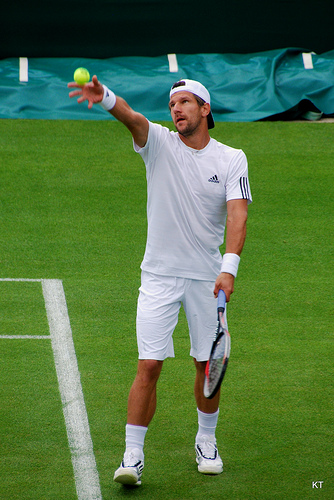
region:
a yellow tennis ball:
[44, 61, 107, 92]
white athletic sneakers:
[105, 416, 278, 499]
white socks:
[105, 393, 277, 481]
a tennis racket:
[174, 260, 277, 444]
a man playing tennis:
[53, 50, 253, 395]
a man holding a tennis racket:
[101, 84, 249, 384]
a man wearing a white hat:
[133, 62, 245, 155]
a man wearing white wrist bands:
[58, 61, 276, 316]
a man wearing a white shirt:
[76, 58, 257, 283]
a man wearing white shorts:
[89, 40, 252, 422]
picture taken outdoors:
[19, 315, 324, 494]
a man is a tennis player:
[94, 317, 284, 480]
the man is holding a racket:
[142, 339, 272, 413]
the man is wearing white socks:
[127, 412, 262, 475]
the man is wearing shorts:
[125, 341, 292, 391]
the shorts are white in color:
[127, 326, 235, 351]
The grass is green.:
[269, 325, 303, 445]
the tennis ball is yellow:
[62, 58, 147, 115]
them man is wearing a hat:
[165, 79, 318, 152]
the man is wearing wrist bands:
[217, 256, 314, 293]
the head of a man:
[161, 69, 215, 144]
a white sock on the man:
[194, 402, 220, 442]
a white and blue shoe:
[189, 433, 226, 475]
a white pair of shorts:
[131, 264, 232, 365]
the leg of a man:
[114, 276, 181, 429]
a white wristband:
[217, 250, 245, 278]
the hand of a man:
[208, 270, 241, 303]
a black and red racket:
[195, 286, 233, 405]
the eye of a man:
[180, 93, 190, 106]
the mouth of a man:
[170, 114, 189, 125]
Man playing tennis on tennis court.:
[62, 62, 265, 488]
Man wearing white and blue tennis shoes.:
[104, 436, 239, 486]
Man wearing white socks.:
[113, 405, 242, 447]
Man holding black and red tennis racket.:
[189, 276, 252, 406]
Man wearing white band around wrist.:
[216, 247, 247, 277]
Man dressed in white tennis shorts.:
[121, 259, 240, 365]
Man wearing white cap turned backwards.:
[164, 72, 226, 128]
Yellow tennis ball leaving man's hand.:
[68, 63, 96, 88]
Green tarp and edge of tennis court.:
[207, 48, 332, 130]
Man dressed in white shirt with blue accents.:
[132, 114, 258, 285]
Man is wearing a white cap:
[153, 65, 242, 133]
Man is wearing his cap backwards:
[151, 69, 248, 149]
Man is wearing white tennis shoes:
[94, 422, 292, 495]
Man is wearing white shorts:
[105, 267, 264, 376]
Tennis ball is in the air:
[65, 56, 97, 96]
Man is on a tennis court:
[31, 60, 316, 498]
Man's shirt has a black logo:
[197, 165, 223, 192]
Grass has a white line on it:
[33, 368, 121, 497]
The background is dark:
[185, 5, 289, 40]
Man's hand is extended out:
[52, 59, 163, 166]